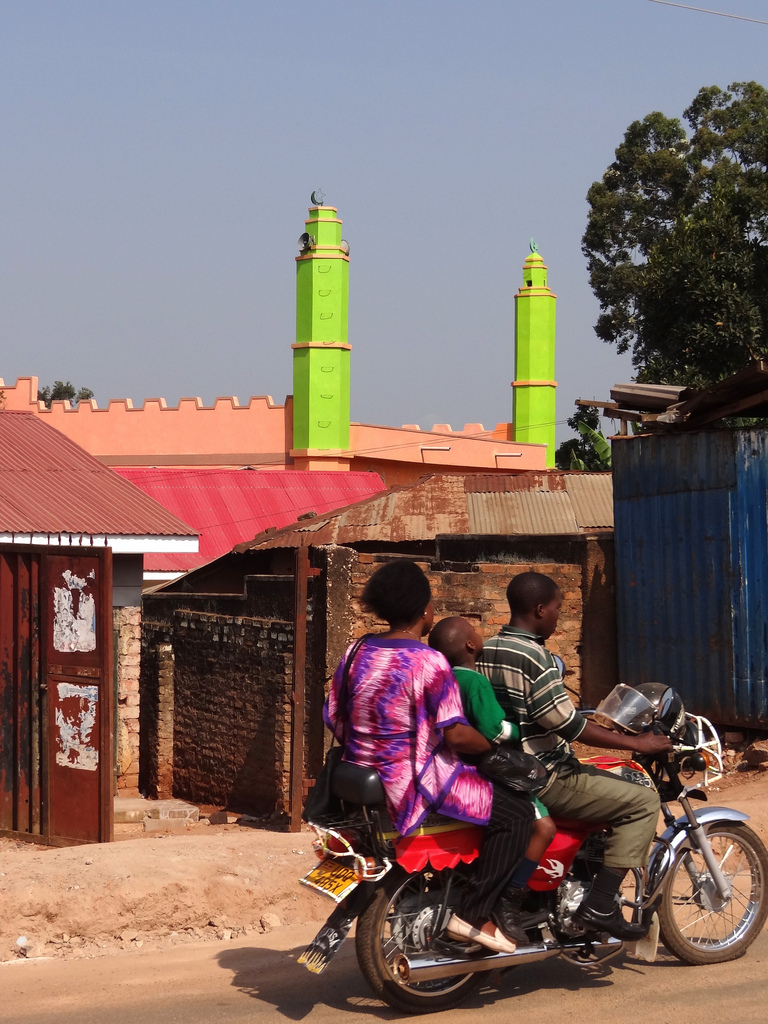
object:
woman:
[323, 558, 536, 961]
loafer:
[445, 912, 514, 955]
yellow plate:
[302, 855, 358, 898]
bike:
[300, 681, 768, 1012]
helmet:
[593, 681, 686, 738]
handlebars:
[575, 706, 677, 766]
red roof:
[109, 466, 388, 573]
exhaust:
[393, 937, 625, 986]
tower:
[291, 187, 355, 471]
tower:
[512, 233, 559, 472]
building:
[0, 375, 548, 475]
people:
[323, 560, 672, 954]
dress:
[325, 635, 495, 843]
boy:
[427, 614, 557, 943]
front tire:
[653, 808, 768, 964]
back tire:
[357, 865, 489, 1010]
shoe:
[570, 901, 646, 942]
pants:
[529, 761, 661, 870]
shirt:
[454, 668, 520, 744]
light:
[313, 829, 374, 879]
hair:
[358, 559, 435, 631]